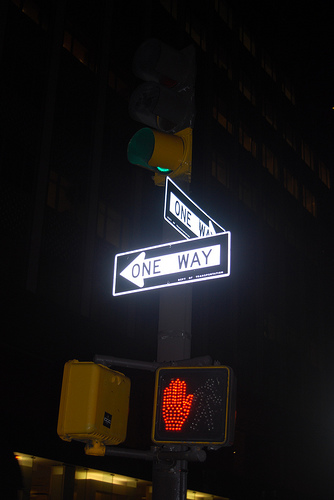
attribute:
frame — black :
[8, 425, 262, 498]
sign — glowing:
[161, 172, 226, 241]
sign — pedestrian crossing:
[147, 360, 234, 451]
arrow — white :
[117, 243, 239, 279]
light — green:
[124, 28, 197, 184]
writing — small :
[178, 270, 224, 281]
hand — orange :
[152, 385, 208, 421]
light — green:
[127, 128, 191, 182]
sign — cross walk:
[123, 166, 250, 320]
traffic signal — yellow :
[125, 38, 198, 187]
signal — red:
[149, 361, 234, 447]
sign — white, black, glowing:
[109, 228, 235, 299]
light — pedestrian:
[148, 362, 238, 449]